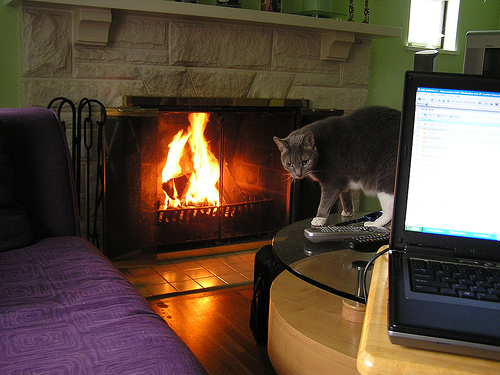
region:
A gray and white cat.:
[272, 105, 404, 228]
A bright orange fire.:
[158, 109, 223, 212]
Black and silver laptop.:
[386, 70, 498, 359]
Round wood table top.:
[268, 246, 378, 373]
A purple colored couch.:
[0, 105, 211, 373]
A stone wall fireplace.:
[21, 8, 371, 259]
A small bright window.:
[404, 0, 464, 55]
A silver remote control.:
[303, 224, 377, 241]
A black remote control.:
[345, 228, 390, 254]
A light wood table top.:
[357, 238, 499, 374]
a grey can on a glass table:
[270, 102, 399, 233]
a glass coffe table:
[268, 207, 390, 374]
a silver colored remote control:
[298, 218, 390, 244]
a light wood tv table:
[354, 240, 498, 373]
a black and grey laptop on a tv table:
[385, 68, 499, 356]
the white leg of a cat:
[364, 191, 394, 227]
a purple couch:
[0, 105, 211, 374]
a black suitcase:
[248, 243, 286, 348]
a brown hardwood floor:
[144, 279, 276, 373]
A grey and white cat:
[269, 90, 403, 233]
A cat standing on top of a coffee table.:
[259, 90, 419, 347]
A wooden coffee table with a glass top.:
[262, 204, 403, 373]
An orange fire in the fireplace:
[154, 113, 262, 220]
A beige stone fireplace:
[19, 3, 406, 282]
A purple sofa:
[1, 102, 223, 373]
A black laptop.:
[391, 65, 498, 356]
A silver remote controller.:
[298, 222, 388, 246]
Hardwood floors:
[141, 284, 284, 373]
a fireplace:
[39, 16, 362, 253]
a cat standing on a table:
[279, 98, 384, 218]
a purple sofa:
[3, 108, 200, 371]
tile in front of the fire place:
[130, 251, 250, 283]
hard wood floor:
[176, 301, 233, 353]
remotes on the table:
[306, 221, 386, 251]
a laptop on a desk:
[389, 74, 498, 371]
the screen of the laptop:
[401, 73, 496, 237]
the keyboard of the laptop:
[406, 252, 483, 300]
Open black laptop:
[387, 68, 499, 365]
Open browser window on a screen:
[405, 85, 499, 239]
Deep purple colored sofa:
[0, 104, 209, 372]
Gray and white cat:
[272, 103, 402, 228]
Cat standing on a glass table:
[270, 104, 403, 229]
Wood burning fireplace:
[98, 90, 347, 263]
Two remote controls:
[307, 220, 391, 251]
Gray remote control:
[302, 223, 384, 241]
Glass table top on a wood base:
[265, 208, 395, 373]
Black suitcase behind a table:
[248, 240, 356, 344]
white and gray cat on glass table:
[271, 102, 396, 225]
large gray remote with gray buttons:
[302, 221, 387, 241]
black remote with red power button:
[341, 231, 387, 247]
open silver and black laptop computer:
[385, 68, 497, 361]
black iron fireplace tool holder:
[43, 96, 103, 248]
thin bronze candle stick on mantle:
[345, 0, 355, 18]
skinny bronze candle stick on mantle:
[365, 0, 370, 19]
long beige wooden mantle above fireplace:
[5, 0, 400, 60]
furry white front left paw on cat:
[310, 214, 325, 226]